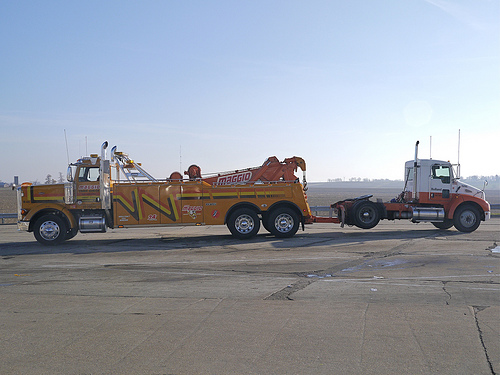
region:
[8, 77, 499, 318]
a tow truck on the road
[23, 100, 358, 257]
an orange tow truck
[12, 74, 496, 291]
a truck towing an 18 wheeler cab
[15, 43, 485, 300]
an 18 wheeler cab being towed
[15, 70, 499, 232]
a cab hooked up to a truck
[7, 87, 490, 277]
a cab hooked up to a tow truck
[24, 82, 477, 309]
a tow truck at work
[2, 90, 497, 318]
a tow truck parked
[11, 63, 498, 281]
a tow truck parked on the road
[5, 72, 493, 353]
tow truck parked on street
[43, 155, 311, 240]
truck tow truck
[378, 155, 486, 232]
truck is red and white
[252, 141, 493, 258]
tow truck is towing a truck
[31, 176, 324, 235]
orange tow truck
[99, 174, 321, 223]
yellow and green stripes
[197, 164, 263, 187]
MAGGIO written in red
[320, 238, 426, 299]
puddle on the ground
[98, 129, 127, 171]
two pipes on the truck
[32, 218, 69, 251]
truck has silver hubcaps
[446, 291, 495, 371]
crack in the cement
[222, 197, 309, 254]
black rubber tires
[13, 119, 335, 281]
an orange truck on the cement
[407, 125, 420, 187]
exhaust pipe on a truck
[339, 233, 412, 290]
water on the ground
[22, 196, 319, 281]
shadows of the trucks on the ground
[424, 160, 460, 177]
window of the truck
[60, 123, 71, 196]
antenna on the truck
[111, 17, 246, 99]
bright blue sky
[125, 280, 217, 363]
cement on the ground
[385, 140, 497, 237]
truck is orange and white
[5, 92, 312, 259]
the truck is orange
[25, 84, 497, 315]
the truck is towing other truck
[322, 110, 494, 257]
truck is hooked on other truck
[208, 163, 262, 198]
red letters on truck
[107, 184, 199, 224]
zig zag lines on truck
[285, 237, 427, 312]
the ground is wet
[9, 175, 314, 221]
lines are red orange and black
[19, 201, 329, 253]
tires of truck are black and silver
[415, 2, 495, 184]
sun is shining on right side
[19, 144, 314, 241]
the truck is facing left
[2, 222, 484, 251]
the trucks are casting a shadow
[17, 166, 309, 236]
the truck is painted orange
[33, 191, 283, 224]
stripes run across the truck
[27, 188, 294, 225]
the lines are yellow and black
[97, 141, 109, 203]
an exhaust pipe is on the truck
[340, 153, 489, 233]
a truck is behind the other truck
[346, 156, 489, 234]
the truck is red and white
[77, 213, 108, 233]
a cylinder is on the truck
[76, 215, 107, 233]
the cylinder is made of chrome